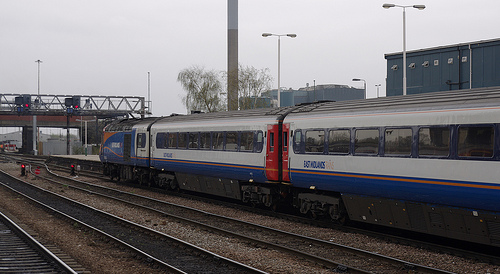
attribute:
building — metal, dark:
[382, 36, 497, 103]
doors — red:
[265, 122, 292, 181]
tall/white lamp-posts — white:
[261, 27, 300, 110]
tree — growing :
[176, 66, 225, 112]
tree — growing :
[224, 63, 270, 106]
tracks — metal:
[4, 153, 496, 269]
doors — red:
[256, 122, 364, 209]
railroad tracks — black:
[142, 189, 439, 264]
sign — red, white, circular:
[29, 165, 46, 179]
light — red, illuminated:
[68, 162, 75, 167]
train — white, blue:
[97, 86, 499, 256]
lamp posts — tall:
[259, 28, 303, 108]